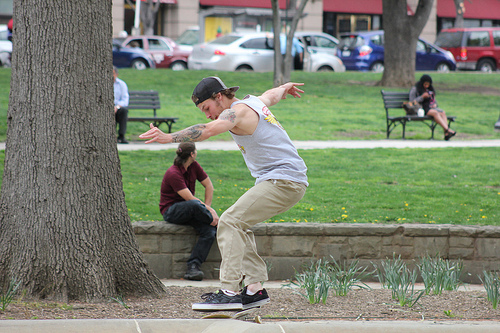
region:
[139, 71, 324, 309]
Skateboarder in the park.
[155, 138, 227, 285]
Person turned away from the skateboarder.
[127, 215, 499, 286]
Cement wall where man behind skateboarder.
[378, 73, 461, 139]
Woman sitting on a bench.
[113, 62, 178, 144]
Man sitting on a bench.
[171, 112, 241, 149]
Tatoos on the man.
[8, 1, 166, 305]
Large tree next to the man.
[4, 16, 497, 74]
Cars parked in the background.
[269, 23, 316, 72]
Person getting into car.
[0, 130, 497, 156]
Path in the park.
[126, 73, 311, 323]
skateboarder with arms extended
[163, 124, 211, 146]
tattoo on man's arm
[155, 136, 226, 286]
man sitting on stone wall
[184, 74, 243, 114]
backwards cap on head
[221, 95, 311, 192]
light gray tank top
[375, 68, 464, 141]
woman sitting on park bench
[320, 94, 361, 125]
green grass on ground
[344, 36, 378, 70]
blue car on street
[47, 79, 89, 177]
bark on tree trunk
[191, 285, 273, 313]
black sneakers with white sole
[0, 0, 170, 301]
The large trunk of an ash tree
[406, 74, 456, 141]
A woman on a bench in the distance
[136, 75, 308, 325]
A guy doing a trick on a skateboard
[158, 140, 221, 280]
A guy sitting on a stone edge of a walkway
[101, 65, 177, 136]
A guy sitting on a bench behind the tree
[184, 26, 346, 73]
A silver car parked on the road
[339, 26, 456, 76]
A blue SUV parked on the road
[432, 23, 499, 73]
A red SUV parked on the road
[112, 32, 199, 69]
A red car parked across the street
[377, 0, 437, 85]
A tree behind the woman on a bench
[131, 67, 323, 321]
a young man on a skateboard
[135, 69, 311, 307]
a tattooed young man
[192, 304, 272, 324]
a skateboard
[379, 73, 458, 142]
a woman sitting on a park bench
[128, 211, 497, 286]
a stone retaining wall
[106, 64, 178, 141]
a man sitting on a park bench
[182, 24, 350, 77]
a silver parked car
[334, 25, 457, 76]
a blue parked car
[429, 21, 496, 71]
a red SUV with brake lights on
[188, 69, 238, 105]
a black and white cap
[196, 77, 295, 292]
this is a man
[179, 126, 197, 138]
this is a tattoo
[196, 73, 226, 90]
this is a cap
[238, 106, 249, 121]
the man is light skinned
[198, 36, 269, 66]
this is a car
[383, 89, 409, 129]
this is a bench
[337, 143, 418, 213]
this is a grass area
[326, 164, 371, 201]
the grass is green in color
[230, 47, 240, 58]
the car is white in color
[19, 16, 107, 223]
this is a tree